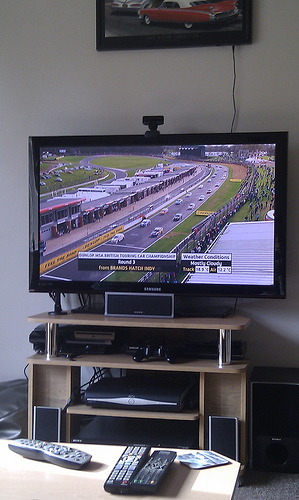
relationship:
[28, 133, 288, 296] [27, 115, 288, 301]
frame on television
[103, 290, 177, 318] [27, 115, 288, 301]
speaker under television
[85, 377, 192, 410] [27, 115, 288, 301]
box under television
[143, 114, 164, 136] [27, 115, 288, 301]
camera on top of television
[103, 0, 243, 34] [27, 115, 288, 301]
picture above television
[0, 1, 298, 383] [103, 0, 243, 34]
wall under picture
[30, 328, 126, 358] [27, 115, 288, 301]
system under television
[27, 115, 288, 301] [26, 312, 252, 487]
television on center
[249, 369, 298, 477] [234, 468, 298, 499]
speaker on carpet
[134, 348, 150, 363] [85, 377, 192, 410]
controller above box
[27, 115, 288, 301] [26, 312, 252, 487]
television on a center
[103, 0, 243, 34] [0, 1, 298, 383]
picture on wall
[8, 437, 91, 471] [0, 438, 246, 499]
remote on table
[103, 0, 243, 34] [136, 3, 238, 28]
picture with red car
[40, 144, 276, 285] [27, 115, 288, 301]
game on television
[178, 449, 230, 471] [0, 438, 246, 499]
coaster on table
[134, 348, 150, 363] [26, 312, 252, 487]
controller on center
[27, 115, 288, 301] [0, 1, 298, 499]
television in room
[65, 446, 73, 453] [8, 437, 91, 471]
button on remote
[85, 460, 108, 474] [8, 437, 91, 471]
shadow next to remote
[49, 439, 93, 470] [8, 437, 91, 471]
head of remote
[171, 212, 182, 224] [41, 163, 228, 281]
car on road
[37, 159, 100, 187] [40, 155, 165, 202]
people in grass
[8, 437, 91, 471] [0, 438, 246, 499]
remote on a table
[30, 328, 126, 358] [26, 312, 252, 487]
system on a center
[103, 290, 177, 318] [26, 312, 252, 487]
speaker on a center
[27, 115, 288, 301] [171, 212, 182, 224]
television with car